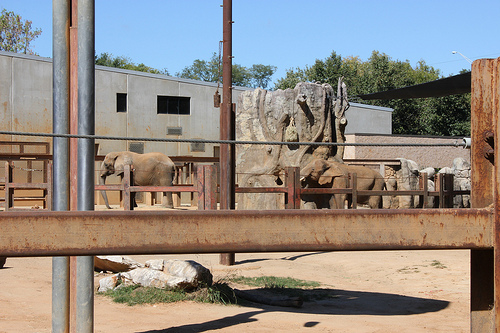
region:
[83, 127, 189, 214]
Elephant inside a pen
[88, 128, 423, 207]
two elephants in a pen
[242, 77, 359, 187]
Rock in front of a elephant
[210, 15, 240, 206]
metal pole in the ground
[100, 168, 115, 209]
elephant with a long trunk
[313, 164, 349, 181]
elephant with large ears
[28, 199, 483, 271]
Metal pole holding a fence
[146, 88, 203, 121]
window on a building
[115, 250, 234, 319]
Rock on a ground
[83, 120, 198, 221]
Elephant standing on ground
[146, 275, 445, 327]
large shadow on the ground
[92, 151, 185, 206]
an elephant standing by the wall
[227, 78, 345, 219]
large stone in the middle of the dirt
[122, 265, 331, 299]
patches of dirt on the ground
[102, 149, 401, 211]
elephants in the pen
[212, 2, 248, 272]
a brown metal pole in the middle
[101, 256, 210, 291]
rocks in the pen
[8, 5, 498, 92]
bright blue sky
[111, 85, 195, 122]
windows on a building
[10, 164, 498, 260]
iron fence pole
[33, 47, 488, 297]
Elephants are in a secure enclosure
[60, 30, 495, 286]
Elephants walking around the enclosure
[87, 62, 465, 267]
A male and a female elephant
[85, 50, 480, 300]
The elephants are looking for food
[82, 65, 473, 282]
The elephants are preparing to be fed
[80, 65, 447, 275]
The elephants are enjoying the sunshine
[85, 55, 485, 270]
The elephants are in a zoo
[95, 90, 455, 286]
The elephants are all fully grown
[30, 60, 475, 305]
The elephants are by a big building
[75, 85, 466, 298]
The elephants are out in daytime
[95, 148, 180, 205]
Gray elephant behind fence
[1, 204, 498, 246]
Rusted metal bar on fence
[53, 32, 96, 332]
Rounded silver pipes on fence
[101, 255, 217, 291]
Tan rock on dirt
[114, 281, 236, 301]
Patch of green grass near rock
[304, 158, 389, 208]
Elephant inside an enclosure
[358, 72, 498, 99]
Shade cover over enclosure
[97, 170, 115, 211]
Long trunk on elephant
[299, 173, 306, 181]
White tusk on elephant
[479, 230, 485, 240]
Rust spot on fence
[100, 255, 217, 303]
pile of rocks on the ground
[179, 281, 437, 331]
shadow in the dirt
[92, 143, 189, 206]
an elephant standing alone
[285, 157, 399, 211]
an elephant standing by a rock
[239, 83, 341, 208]
a large rock structure in the pen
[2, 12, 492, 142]
tops of green trees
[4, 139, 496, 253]
iron fences around the pen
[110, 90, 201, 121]
black windows on a building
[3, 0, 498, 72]
blue sky above